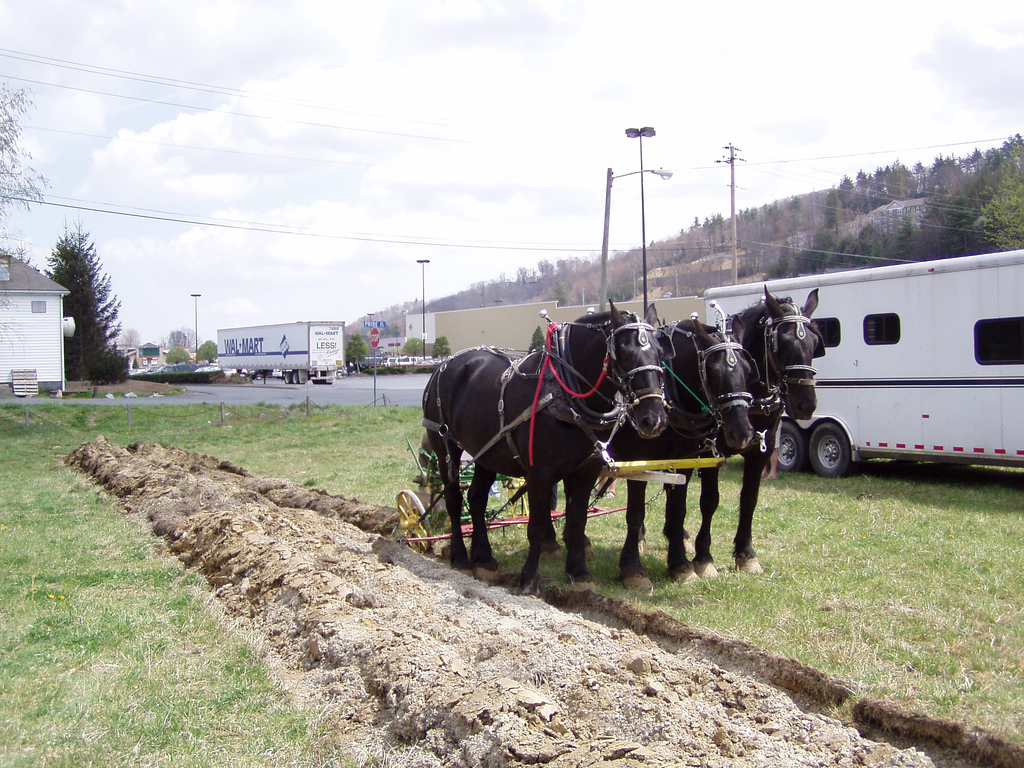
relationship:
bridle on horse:
[510, 298, 616, 473] [433, 305, 664, 584]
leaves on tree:
[969, 169, 1017, 215] [928, 155, 1021, 214]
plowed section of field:
[57, 451, 317, 607] [70, 432, 1001, 759]